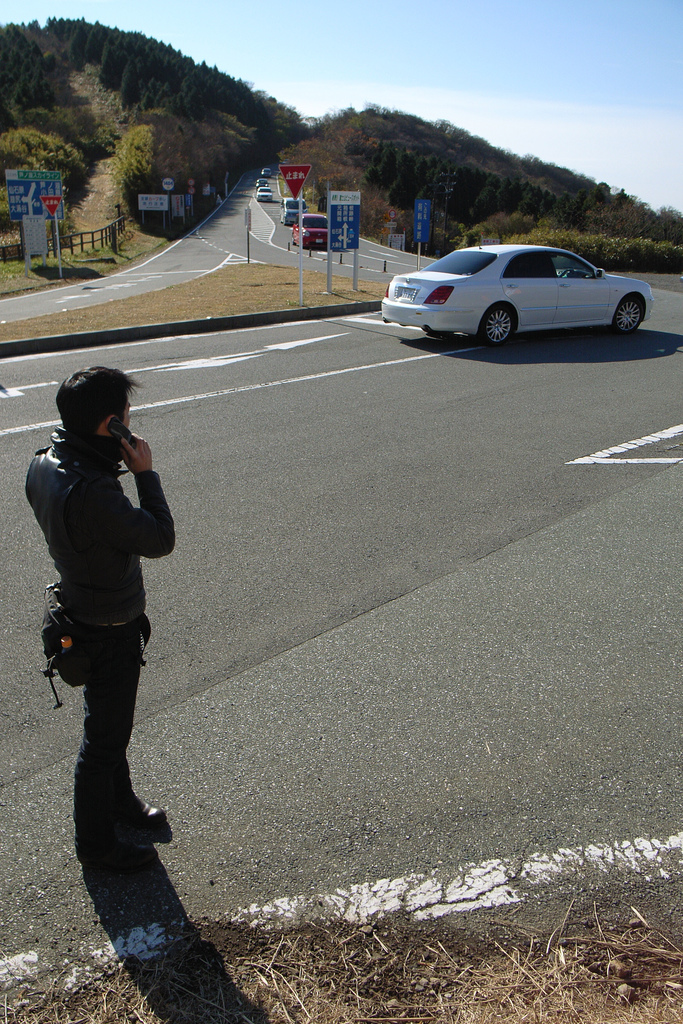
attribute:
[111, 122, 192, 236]
tree — in woods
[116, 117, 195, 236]
tree —   in woods,  in woods, in woods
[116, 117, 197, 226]
tree — in woods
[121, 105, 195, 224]
tree —   in woods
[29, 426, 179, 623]
jacket — leather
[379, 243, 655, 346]
car — white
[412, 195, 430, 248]
sign — blue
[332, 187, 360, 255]
sign — blue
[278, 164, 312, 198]
sign — red, triangle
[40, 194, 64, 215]
sign — triangle, red